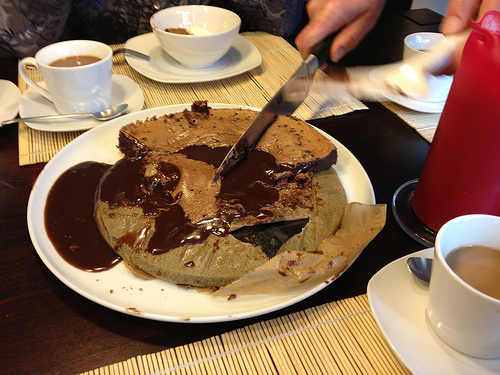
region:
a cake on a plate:
[80, 105, 387, 341]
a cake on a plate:
[37, 47, 297, 272]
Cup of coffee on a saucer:
[12, 40, 148, 135]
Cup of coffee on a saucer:
[121, 3, 266, 85]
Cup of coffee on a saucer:
[362, 212, 499, 372]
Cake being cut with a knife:
[23, 99, 376, 326]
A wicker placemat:
[13, 28, 373, 166]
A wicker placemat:
[76, 289, 410, 374]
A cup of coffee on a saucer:
[368, 28, 455, 113]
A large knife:
[209, 30, 334, 180]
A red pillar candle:
[408, 10, 498, 231]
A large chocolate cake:
[94, 105, 344, 288]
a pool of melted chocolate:
[43, 135, 140, 286]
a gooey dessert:
[98, 89, 338, 204]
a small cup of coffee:
[378, 196, 498, 355]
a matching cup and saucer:
[7, 44, 152, 134]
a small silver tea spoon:
[11, 105, 143, 127]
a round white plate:
[23, 92, 380, 343]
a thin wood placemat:
[32, 310, 394, 374]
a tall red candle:
[396, 7, 498, 239]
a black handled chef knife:
[216, 23, 353, 194]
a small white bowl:
[140, 0, 252, 73]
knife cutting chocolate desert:
[210, 25, 330, 175]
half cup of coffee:
[421, 210, 496, 360]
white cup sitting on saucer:
[422, 210, 493, 360]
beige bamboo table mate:
[75, 290, 403, 370]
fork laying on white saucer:
[112, 45, 154, 63]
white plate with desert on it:
[25, 100, 376, 321]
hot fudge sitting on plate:
[96, 106, 348, 289]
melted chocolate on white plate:
[40, 160, 121, 270]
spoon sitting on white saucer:
[405, 252, 433, 283]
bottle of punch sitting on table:
[407, 10, 499, 236]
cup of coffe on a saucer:
[35, 28, 145, 119]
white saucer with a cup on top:
[20, 70, 117, 136]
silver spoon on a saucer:
[10, 102, 135, 124]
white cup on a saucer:
[157, 1, 237, 61]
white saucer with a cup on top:
[150, 41, 265, 73]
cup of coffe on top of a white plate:
[430, 215, 495, 350]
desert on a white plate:
[150, 115, 330, 200]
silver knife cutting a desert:
[225, 20, 355, 167]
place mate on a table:
[122, 306, 377, 371]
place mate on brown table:
[251, 5, 292, 71]